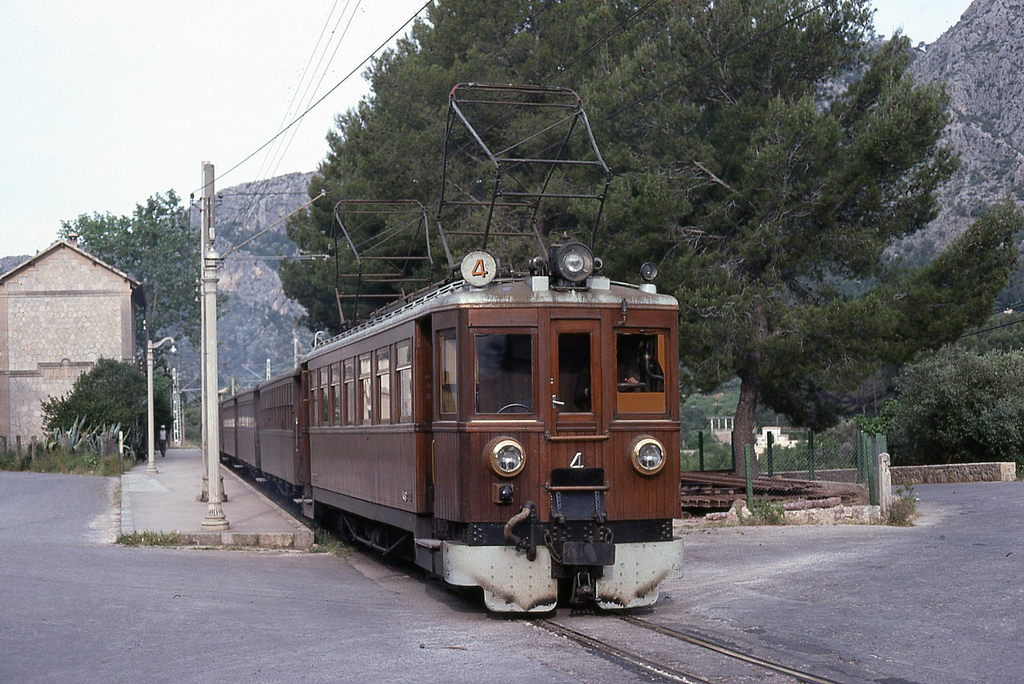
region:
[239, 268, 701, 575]
brown train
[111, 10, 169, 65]
white clouds in the blue sky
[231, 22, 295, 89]
white clouds in the blue sky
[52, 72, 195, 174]
white clouds in the blue sky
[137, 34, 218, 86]
white clouds in the blue sky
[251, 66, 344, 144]
white clouds in the blue sky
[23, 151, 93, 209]
white clouds in the blue sky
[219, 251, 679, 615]
An old type of train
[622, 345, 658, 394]
Motorman of the train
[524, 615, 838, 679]
Rail tracks under the train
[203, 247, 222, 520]
Lamp and lamppost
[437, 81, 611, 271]
Pentograph on top of the train car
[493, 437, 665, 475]
Front lights of the train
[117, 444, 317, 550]
Railway platform at a station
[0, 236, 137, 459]
Building of the railway station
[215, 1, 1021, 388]
Rocky hills in the background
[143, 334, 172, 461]
Light on the platform and its pole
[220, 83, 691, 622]
Antique wooden tram.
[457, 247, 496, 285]
Red number four on a white round sign.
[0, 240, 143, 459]
Gray stone building.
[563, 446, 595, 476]
Silver number four attached to front of train.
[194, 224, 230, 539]
Tall white sign post.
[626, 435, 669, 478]
Round headlight with gold frame.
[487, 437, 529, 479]
Round headlight with gold frame.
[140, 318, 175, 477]
Tall white lamp post on top of pavement.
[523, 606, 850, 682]
Railroad tracks crossing a street.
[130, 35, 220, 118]
white clouds in blue sky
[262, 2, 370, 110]
white clouds in blue sky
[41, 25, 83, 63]
white clouds in blue sky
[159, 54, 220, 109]
white clouds in blue sky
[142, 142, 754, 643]
this is a train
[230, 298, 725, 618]
the train is brown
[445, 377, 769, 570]
the headlights are gray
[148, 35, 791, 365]
the train is on wires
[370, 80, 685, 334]
the train is electrical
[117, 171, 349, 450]
the pole is metal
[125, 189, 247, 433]
the pole is gray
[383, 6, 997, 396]
the trees are very large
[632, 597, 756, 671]
these are rails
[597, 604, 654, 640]
the rail is metal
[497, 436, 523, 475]
The left headlight of the trolley.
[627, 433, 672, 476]
The right headlight of the trolley.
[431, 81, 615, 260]
The electrical structure near the front top of the trolley.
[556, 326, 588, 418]
The center window of the trolley.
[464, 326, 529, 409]
The front left window of the trolley.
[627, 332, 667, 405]
The front right window of the trolley.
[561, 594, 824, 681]
The tracks in front of the trolley.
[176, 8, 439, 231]
The wires above the trolley and the street.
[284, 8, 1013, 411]
The big tree to the right of the trolley.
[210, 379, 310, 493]
The cars attached to the trolley.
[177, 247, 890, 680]
train on the tracks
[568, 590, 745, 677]
a set of tracks